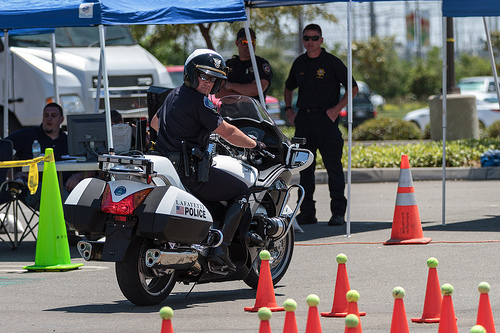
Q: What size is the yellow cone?
A: Large.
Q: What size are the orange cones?
A: Small.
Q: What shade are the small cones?
A: Orange.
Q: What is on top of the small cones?
A: Balls.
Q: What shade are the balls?
A: Yellow.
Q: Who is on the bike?
A: A police officer.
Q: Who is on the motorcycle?
A: The officer.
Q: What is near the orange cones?
A: The motorcycle.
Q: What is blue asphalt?
A: The parking lot.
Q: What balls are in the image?
A: Tennis balls.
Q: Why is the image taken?
A: Rememberance.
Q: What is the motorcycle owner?
A: Police.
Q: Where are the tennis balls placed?
A: Orange cones topped.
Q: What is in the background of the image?
A: Flowers.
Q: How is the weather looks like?
A: Sunny.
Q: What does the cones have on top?
A: Tennis ball.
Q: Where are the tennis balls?
A: On the cones.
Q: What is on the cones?
A: Tennis balls.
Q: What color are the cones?
A: White, green, and orange.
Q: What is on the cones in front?
A: Balls.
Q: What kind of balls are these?
A: Tennis balls.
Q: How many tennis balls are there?
A: Thirteen.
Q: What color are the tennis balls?
A: Green.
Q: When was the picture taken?
A: Daytime.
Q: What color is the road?
A: Black.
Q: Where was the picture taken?
A: At an outdoor event.